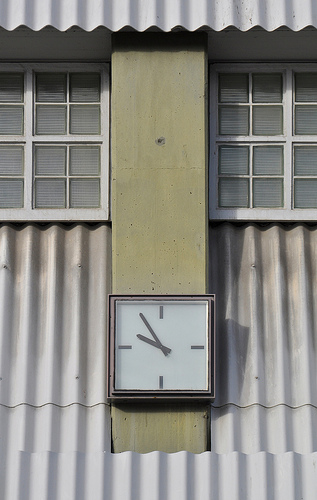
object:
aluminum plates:
[209, 224, 314, 451]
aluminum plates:
[1, 221, 109, 451]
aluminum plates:
[0, 451, 316, 499]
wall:
[1, 1, 311, 496]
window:
[0, 59, 102, 209]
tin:
[2, 222, 315, 500]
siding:
[3, 0, 316, 36]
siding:
[2, 402, 317, 413]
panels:
[209, 222, 317, 452]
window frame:
[207, 61, 316, 220]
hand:
[136, 332, 171, 356]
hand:
[138, 312, 168, 357]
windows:
[2, 56, 316, 210]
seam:
[0, 399, 107, 411]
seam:
[211, 397, 317, 411]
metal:
[0, 221, 112, 405]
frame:
[103, 290, 218, 402]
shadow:
[111, 34, 207, 51]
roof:
[1, 1, 316, 30]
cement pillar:
[111, 30, 208, 454]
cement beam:
[111, 48, 212, 159]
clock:
[102, 288, 217, 404]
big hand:
[134, 312, 172, 357]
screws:
[77, 264, 81, 268]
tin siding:
[0, 222, 111, 231]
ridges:
[42, 219, 65, 453]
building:
[1, 0, 316, 497]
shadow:
[213, 315, 249, 404]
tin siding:
[203, 224, 315, 230]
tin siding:
[209, 448, 316, 457]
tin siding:
[0, 450, 317, 461]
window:
[211, 65, 312, 217]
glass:
[216, 140, 251, 173]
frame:
[206, 60, 219, 217]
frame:
[92, 55, 110, 211]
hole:
[157, 136, 166, 146]